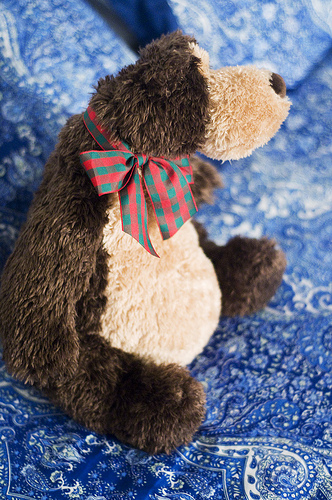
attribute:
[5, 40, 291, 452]
teddy bear — tan, brown, stuffed, sitting, cream, beige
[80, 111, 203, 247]
bow — red, green, plaid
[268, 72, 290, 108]
nose — brown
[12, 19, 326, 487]
bedspread — blue, white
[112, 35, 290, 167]
head — brown, stuffed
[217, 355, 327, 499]
design — white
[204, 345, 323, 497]
paisley — blue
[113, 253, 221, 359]
tummy — beige, tan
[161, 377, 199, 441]
paw — dark brown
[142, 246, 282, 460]
leg — brown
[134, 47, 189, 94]
ear — brown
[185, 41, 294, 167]
face — tan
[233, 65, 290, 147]
snout — cream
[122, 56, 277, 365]
fur — beige, cream